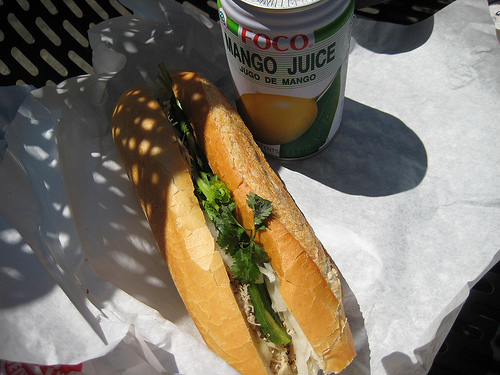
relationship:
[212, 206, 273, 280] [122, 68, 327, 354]
lettuce in sandwhich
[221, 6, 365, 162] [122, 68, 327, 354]
can near sandwhich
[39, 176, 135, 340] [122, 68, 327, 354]
paper holding sandwhich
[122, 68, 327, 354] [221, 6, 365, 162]
sandwhich near can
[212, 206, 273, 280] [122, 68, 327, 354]
lettuce on sandwhich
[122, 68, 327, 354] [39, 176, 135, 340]
sandwhich on paper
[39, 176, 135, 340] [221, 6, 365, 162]
paper holding can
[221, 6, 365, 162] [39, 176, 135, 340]
can on paper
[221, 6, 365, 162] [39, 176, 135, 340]
can in paper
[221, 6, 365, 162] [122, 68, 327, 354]
can next to sandwhich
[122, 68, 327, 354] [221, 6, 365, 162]
sandwhich by can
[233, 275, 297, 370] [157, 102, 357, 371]
cheese in sandwich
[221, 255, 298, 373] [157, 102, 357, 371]
meat in sandwich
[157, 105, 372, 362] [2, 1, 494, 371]
lunch on park bench